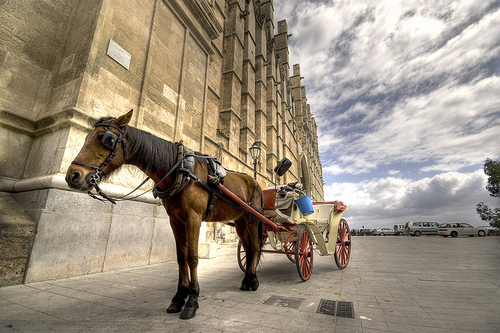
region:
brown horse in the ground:
[66, 108, 268, 311]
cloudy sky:
[322, 18, 425, 149]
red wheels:
[293, 231, 320, 278]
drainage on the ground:
[320, 297, 359, 326]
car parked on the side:
[368, 218, 478, 240]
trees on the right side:
[473, 150, 497, 240]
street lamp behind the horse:
[247, 138, 267, 176]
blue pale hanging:
[293, 190, 321, 222]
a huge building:
[187, 13, 294, 121]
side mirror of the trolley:
[266, 150, 292, 183]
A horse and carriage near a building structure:
[58, 105, 357, 327]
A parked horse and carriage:
[61, 104, 358, 325]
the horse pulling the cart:
[63, 103, 265, 318]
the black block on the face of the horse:
[101, 128, 120, 150]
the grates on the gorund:
[264, 292, 360, 322]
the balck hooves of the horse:
[162, 270, 259, 322]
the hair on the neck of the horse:
[128, 126, 174, 173]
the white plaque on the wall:
[101, 36, 137, 70]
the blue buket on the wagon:
[292, 193, 314, 220]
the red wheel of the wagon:
[290, 224, 320, 284]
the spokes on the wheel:
[337, 227, 348, 269]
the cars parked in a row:
[351, 217, 498, 245]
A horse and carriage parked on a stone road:
[61, 102, 357, 324]